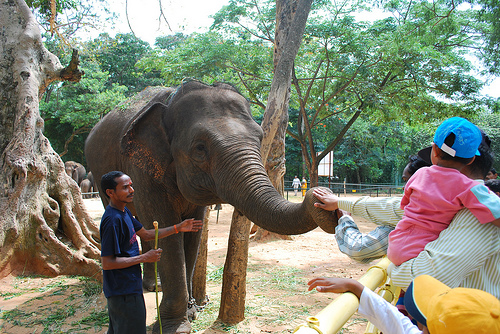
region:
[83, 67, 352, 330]
elephant in a zoo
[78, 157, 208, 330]
man next to elephant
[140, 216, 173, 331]
stick in man's hand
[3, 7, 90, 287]
trunk of a tree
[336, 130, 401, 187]
fence enclosing the elephant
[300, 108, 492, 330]
people outside elephant's fence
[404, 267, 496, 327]
yellow baseball cap on child's head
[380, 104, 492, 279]
baby in man's arms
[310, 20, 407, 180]
green trees behind fence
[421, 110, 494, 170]
blue baseball cap on baby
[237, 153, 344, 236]
The trunk of the elephant.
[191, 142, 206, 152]
The left eye of the elephant.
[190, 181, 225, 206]
The mouth area of the elephant.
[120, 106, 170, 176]
The left ear of the elephant.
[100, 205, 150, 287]
The blue shirt the man is wearing.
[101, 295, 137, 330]
The pants the man is wearing.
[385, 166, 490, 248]
The pink shirt the child is wearing.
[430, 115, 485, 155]
The blue hat the child is wearing.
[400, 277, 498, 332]
The yellow hat the child is wearing.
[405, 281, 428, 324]
The blue stripe on the yellow cap.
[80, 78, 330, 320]
gray elephant being petted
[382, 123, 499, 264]
young child wearing pink outfit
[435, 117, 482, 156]
blue hat with white snap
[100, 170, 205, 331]
man standing next to elephant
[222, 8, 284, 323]
tree trunk beside elephant's face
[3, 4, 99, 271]
gnarled tree trunk beside elephant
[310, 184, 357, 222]
hands on the elephant's trunk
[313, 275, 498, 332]
young child wearing white shirt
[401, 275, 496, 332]
yellow hat with blue and white trim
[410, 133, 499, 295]
man holding young child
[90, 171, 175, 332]
Man next to elephant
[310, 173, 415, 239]
Hand touching elephant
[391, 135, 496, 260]
Man holding kid on shoulder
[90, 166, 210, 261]
Man touching the elephant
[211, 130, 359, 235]
Elephant's trunk touching hand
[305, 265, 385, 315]
Man's hand on fence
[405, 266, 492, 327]
Yellow baseball cap on head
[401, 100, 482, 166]
Child's Blue baseball cap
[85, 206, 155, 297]
Navy blue t shirt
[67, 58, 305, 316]
Grey elephant extending trunk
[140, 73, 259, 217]
this is an elephant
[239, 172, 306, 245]
this is a trunk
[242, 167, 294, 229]
the trunk is long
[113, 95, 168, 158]
this is the ear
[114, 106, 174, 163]
the ear is small in size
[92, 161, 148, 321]
this is a man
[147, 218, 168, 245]
this is a stick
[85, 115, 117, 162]
this is the belly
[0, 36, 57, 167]
this is the tree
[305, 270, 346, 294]
this is the hand